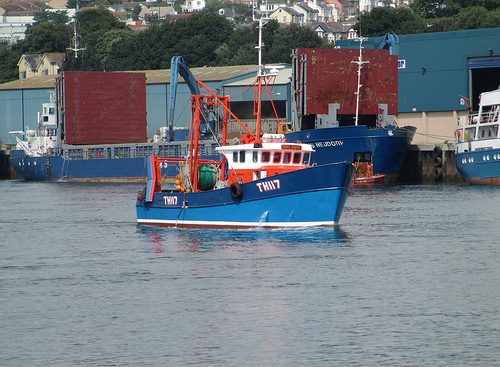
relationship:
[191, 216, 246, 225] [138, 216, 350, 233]
color on boar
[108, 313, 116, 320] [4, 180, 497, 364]
spot on water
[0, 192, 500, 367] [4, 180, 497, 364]
spot on water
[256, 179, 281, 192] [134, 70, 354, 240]
numbers on boat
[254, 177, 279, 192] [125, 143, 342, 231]
numbers on boat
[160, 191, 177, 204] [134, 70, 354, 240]
numbers on boat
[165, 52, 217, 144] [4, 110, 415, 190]
crain on a fishing boat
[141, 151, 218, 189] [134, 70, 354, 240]
orange equipment on a boat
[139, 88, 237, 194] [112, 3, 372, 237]
equipment on a boat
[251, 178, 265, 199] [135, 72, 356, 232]
letter t on side of a boat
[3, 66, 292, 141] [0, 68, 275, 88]
blue building with a brown roof